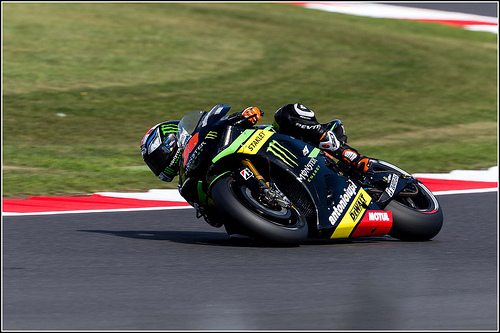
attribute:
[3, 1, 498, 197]
grass — green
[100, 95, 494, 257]
motorcycle — low, black, leaning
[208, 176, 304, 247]
tire — black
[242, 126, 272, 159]
message — Stakley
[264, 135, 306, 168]
logo — Monster energy drink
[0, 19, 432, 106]
grass — short, brown, green, red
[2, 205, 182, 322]
track — smooth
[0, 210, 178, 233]
line — white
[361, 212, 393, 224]
motul — company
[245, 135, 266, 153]
sticker — yellow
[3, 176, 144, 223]
boundary — red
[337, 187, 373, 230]
dewalt — logo